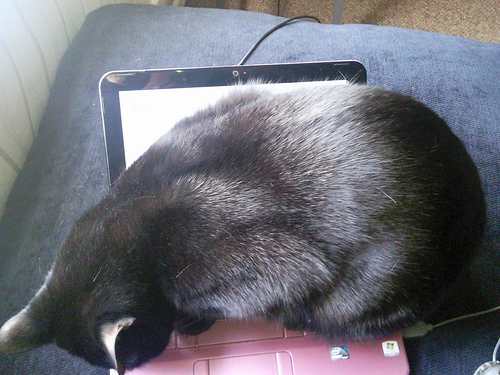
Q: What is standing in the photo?
A: The cat.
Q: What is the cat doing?
A: Sniffing.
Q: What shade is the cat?
A: Black.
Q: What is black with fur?
A: The cat.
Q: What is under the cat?
A: The computer.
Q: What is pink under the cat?
A: Computer board.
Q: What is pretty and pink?
A: Small laptop.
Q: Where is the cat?
A: On the laptop.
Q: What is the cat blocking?
A: The laptop screen.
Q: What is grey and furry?
A: The cat.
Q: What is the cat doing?
A: Laying on laptop.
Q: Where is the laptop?
A: On bed.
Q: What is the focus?
A: Cat on pink netbook.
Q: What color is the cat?
A: Black.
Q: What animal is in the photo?
A: Cat.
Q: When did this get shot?
A: Daytime.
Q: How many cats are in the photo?
A: 1.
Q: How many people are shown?
A: 0.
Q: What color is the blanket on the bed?
A: Blue.